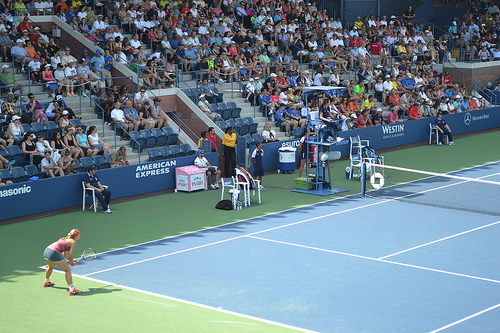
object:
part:
[421, 272, 450, 308]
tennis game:
[2, 2, 500, 333]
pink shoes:
[69, 287, 82, 297]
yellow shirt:
[198, 137, 208, 149]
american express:
[135, 160, 176, 179]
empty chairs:
[146, 148, 164, 162]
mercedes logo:
[464, 113, 472, 126]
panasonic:
[0, 185, 32, 198]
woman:
[21, 132, 39, 161]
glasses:
[29, 135, 33, 137]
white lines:
[432, 304, 500, 332]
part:
[296, 265, 359, 305]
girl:
[64, 125, 85, 159]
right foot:
[68, 289, 81, 295]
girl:
[43, 228, 81, 295]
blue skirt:
[43, 248, 64, 262]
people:
[261, 123, 281, 144]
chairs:
[234, 167, 261, 206]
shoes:
[43, 279, 54, 287]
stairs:
[79, 104, 108, 133]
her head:
[67, 229, 80, 241]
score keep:
[81, 165, 115, 217]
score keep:
[430, 105, 459, 148]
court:
[0, 128, 500, 333]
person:
[222, 127, 238, 178]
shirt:
[207, 133, 217, 149]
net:
[365, 163, 500, 216]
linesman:
[319, 99, 345, 142]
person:
[193, 149, 221, 189]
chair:
[82, 181, 109, 213]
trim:
[0, 104, 500, 333]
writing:
[135, 172, 140, 178]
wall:
[3, 184, 66, 209]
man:
[434, 113, 455, 146]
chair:
[429, 123, 449, 146]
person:
[207, 127, 217, 152]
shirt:
[221, 132, 236, 147]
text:
[135, 166, 141, 172]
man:
[408, 104, 420, 120]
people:
[109, 146, 132, 168]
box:
[175, 165, 206, 193]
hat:
[88, 165, 99, 170]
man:
[84, 166, 113, 214]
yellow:
[224, 138, 236, 145]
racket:
[77, 248, 97, 263]